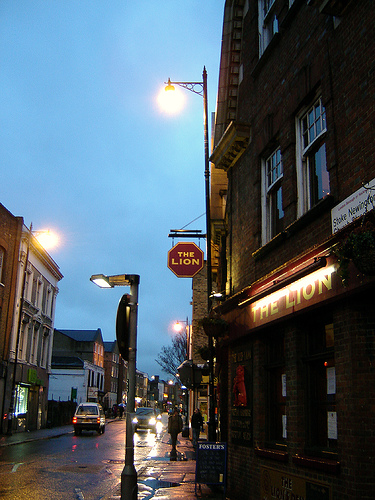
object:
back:
[72, 401, 101, 429]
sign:
[330, 179, 375, 237]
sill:
[293, 451, 345, 473]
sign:
[242, 265, 343, 330]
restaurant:
[212, 210, 374, 500]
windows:
[310, 365, 337, 404]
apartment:
[206, 0, 373, 499]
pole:
[119, 286, 137, 499]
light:
[89, 272, 114, 290]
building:
[49, 326, 104, 409]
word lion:
[282, 268, 335, 309]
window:
[308, 144, 330, 210]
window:
[269, 183, 282, 237]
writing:
[172, 255, 200, 270]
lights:
[72, 416, 76, 425]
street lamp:
[7, 227, 61, 435]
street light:
[154, 82, 186, 120]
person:
[166, 406, 183, 458]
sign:
[195, 440, 228, 483]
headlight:
[147, 416, 157, 426]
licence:
[80, 418, 94, 424]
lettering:
[197, 441, 222, 451]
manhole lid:
[107, 457, 124, 465]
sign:
[166, 240, 203, 280]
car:
[70, 400, 106, 438]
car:
[130, 407, 158, 433]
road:
[0, 415, 169, 499]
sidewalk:
[98, 431, 226, 499]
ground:
[0, 414, 220, 500]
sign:
[114, 291, 132, 363]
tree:
[153, 325, 190, 387]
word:
[249, 296, 280, 322]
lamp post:
[201, 64, 215, 441]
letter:
[251, 303, 261, 326]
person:
[188, 407, 205, 452]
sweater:
[188, 412, 203, 432]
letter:
[258, 302, 270, 320]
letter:
[269, 295, 280, 316]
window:
[24, 271, 30, 300]